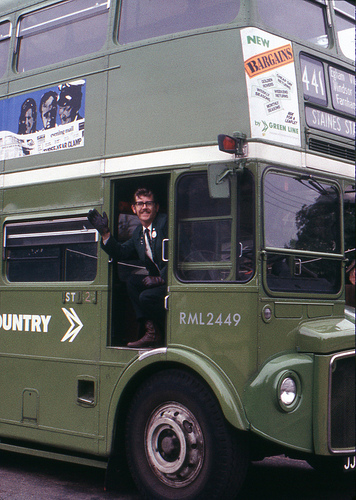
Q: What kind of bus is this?
A: A double decker.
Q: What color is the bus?
A: Green.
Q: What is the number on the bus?
A: 44.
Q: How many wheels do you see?
A: 1.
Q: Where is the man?
A: Standing in the window.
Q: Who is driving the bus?
A: The bus driver.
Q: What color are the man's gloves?
A: Black.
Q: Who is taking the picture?
A: A friend.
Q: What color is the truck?
A: Green.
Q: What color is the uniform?
A: Black.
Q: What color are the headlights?
A: Silver.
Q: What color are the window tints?
A: Black.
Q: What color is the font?
A: White.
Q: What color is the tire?
A: Black.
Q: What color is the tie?
A: Black.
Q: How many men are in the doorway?
A: One.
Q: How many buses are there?
A: One.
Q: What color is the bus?
A: Green.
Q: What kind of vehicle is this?
A: A double-decker bus.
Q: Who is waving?
A: The bus driver.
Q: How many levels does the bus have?
A: Two.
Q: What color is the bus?
A: Green.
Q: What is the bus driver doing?
A: Waving.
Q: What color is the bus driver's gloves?
A: Black.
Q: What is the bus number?
A: 441.